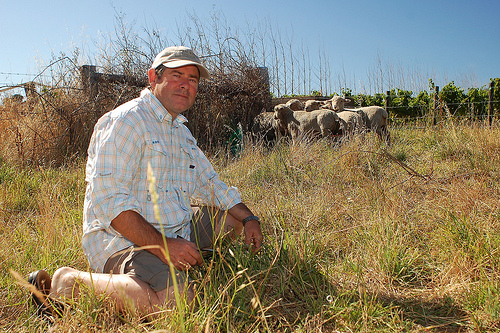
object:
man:
[24, 47, 263, 326]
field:
[0, 112, 500, 332]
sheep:
[252, 96, 390, 148]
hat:
[151, 46, 210, 79]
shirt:
[81, 88, 242, 273]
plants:
[269, 79, 498, 123]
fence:
[0, 67, 499, 129]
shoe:
[27, 269, 77, 324]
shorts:
[103, 204, 226, 292]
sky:
[1, 0, 499, 98]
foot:
[49, 267, 77, 306]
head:
[148, 44, 211, 113]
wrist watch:
[242, 215, 260, 226]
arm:
[193, 142, 254, 222]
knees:
[177, 299, 199, 316]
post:
[81, 64, 100, 118]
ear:
[149, 68, 158, 88]